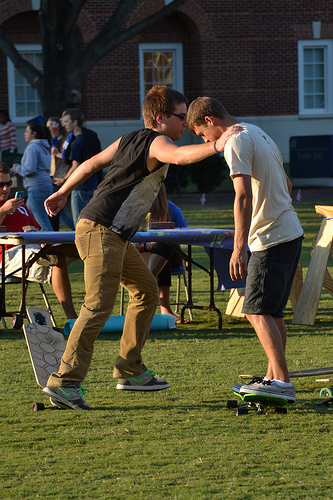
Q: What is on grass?
A: Folding table.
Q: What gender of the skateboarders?
A: Male.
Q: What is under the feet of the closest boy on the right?
A: Skateboard.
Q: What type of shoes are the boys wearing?
A: Sneakers.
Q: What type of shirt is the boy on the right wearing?
A: T-shirt.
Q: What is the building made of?
A: Bricks.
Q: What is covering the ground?
A: Grass.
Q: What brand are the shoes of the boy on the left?
A: Nike.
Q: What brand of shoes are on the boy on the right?
A: Nike.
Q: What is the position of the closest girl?
A: Sitting.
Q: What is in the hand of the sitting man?
A: Cell phone.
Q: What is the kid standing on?
A: Skateboard.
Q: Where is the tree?
A: Near building.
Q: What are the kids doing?
A: Playing on skateboards.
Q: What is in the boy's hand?
A: Cell phone.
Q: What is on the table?
A: A cloth.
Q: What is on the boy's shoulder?
A: A hand.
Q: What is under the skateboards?
A: Grass.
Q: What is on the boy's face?
A: Glasses.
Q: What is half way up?
A: Skateboard.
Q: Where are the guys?
A: On the grass.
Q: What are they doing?
A: Playing.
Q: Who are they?
A: Kids.